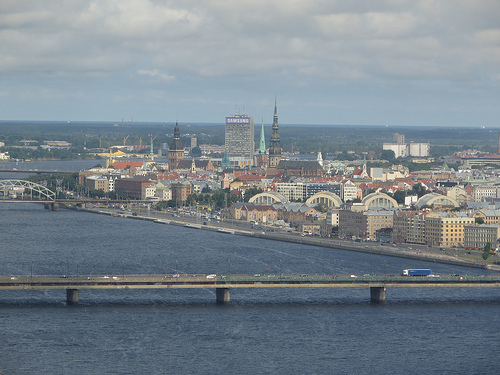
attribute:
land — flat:
[3, 120, 500, 271]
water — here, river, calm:
[1, 203, 500, 374]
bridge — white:
[1, 272, 500, 307]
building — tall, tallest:
[225, 113, 255, 157]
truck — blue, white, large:
[402, 268, 432, 277]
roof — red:
[112, 159, 143, 170]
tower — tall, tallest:
[267, 101, 282, 173]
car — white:
[205, 272, 218, 279]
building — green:
[149, 141, 155, 164]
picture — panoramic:
[2, 2, 497, 372]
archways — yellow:
[248, 190, 458, 209]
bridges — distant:
[1, 165, 169, 213]